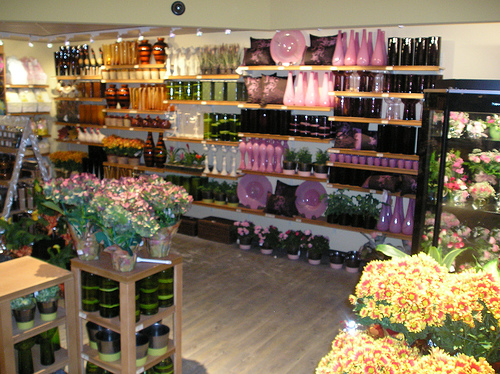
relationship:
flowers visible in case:
[439, 116, 499, 281] [394, 124, 499, 318]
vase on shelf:
[332, 29, 345, 66] [236, 63, 441, 72]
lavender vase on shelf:
[403, 197, 414, 235] [192, 195, 414, 234]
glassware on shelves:
[214, 117, 332, 192] [85, 65, 411, 288]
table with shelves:
[69, 243, 186, 372] [61, 245, 175, 365]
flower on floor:
[305, 232, 328, 266] [170, 232, 377, 372]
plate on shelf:
[295, 171, 326, 223] [196, 194, 413, 242]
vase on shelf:
[258, 137, 278, 180] [126, 70, 341, 192]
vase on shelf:
[371, 28, 386, 68] [53, 62, 441, 237]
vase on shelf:
[354, 25, 371, 68] [53, 62, 441, 237]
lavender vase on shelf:
[344, 30, 357, 66] [53, 62, 441, 237]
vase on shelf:
[330, 26, 346, 67] [53, 62, 441, 237]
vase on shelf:
[317, 70, 330, 109] [53, 62, 441, 237]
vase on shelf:
[305, 68, 316, 107] [53, 62, 441, 237]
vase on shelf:
[291, 67, 304, 108] [53, 62, 441, 237]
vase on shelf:
[281, 68, 293, 107] [53, 62, 441, 237]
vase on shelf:
[272, 138, 282, 173] [53, 62, 441, 237]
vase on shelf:
[266, 140, 275, 173] [53, 62, 441, 237]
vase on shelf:
[258, 137, 268, 169] [53, 62, 441, 237]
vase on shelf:
[251, 138, 258, 169] [53, 62, 441, 237]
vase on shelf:
[245, 135, 255, 169] [53, 62, 441, 237]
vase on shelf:
[238, 135, 249, 170] [53, 62, 441, 237]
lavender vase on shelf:
[402, 196, 415, 234] [53, 62, 441, 237]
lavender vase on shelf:
[389, 196, 403, 233] [53, 62, 441, 237]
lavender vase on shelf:
[376, 202, 390, 231] [53, 62, 441, 237]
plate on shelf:
[272, 27, 303, 66] [232, 63, 438, 73]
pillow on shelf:
[308, 30, 338, 65] [239, 29, 446, 75]